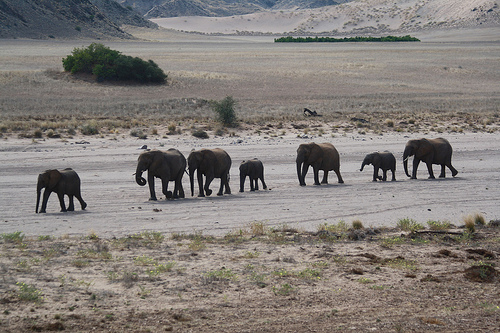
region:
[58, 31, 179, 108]
green plants on desert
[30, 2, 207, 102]
green plants on desert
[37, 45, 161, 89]
green plants on desert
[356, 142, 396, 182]
the elephant is small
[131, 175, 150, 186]
the trunk is curled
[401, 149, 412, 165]
the elephant has tusks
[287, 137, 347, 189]
the elephant is large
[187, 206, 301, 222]
the ground is white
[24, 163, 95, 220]
the elephant is in the lead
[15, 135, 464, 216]
the elephants are walking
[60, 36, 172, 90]
the bush is lush and green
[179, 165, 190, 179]
the elephant has a tail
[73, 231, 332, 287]
the grass is sparce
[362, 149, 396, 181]
baby elephant following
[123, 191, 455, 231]
sand on the g round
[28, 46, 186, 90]
small brushes in the sand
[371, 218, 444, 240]
patches of grass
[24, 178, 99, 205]
small elephant leading others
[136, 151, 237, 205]
two big elephants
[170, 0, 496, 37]
mountains in the background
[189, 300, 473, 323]
gravel on the ground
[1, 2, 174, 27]
rocky hillside in photo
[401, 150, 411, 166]
tusk on the elephant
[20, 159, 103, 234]
elephant on the road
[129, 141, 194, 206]
elephant on the road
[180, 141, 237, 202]
elephant on the road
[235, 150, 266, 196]
elephant on the road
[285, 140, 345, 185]
elephant on the road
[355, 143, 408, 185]
elephant on the road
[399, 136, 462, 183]
elephant on the road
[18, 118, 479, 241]
herd of elephants walking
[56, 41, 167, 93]
large bush with green leaves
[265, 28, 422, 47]
large bush with green leaves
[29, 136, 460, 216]
a group of grey elephants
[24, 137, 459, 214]
a group of elephants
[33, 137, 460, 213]
a group of walking elephants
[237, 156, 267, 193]
a smaller baby elephant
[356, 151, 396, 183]
a smaller baby elephant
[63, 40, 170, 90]
a green bush in the background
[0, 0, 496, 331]
an empty and dry landscape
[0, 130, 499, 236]
a dirt road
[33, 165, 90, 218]
an elephant leading the group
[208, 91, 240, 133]
a small green tree